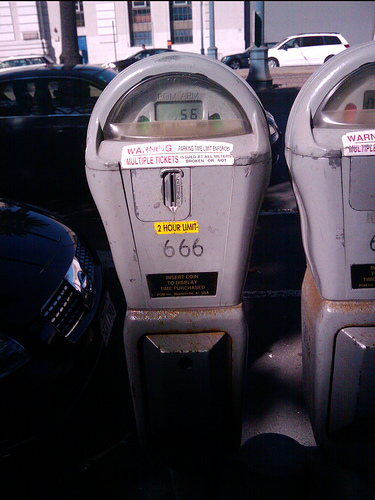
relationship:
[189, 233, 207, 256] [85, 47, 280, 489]
number on parking meter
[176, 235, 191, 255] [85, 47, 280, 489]
number on parking meter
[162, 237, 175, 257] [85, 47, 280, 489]
number on parking meter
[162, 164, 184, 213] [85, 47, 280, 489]
coin slot on parking meter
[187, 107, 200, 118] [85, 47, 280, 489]
number on parking meter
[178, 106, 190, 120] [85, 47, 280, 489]
number on parking meter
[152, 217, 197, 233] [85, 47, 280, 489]
sticker on parking meter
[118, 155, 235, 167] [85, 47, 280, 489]
sticker on parking meter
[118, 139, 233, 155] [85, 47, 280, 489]
sticker on parking meter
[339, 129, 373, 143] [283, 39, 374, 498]
sticker on parking meter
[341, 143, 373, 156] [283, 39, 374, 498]
sticker on parking meter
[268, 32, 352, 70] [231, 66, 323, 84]
car on road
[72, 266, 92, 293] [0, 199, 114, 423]
emblem on car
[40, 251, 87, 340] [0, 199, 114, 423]
grill on car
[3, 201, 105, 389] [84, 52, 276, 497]
car parked near machine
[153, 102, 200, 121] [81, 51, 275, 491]
display on meter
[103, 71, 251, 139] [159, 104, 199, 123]
cover over display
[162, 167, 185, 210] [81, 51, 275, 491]
slot of meter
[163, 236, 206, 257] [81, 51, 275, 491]
666 on meter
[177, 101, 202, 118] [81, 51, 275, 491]
56 on meter